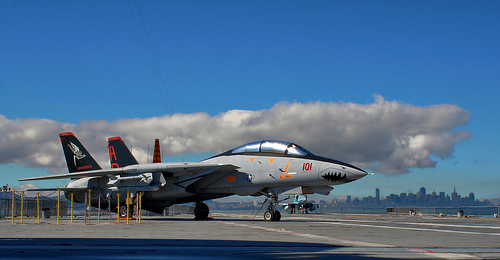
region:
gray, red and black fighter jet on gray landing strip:
[26, 126, 366, 215]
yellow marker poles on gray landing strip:
[0, 178, 156, 235]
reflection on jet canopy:
[216, 128, 314, 164]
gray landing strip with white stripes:
[341, 215, 479, 254]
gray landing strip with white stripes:
[168, 225, 360, 258]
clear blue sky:
[16, 15, 203, 100]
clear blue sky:
[168, 16, 345, 83]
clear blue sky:
[291, 10, 494, 92]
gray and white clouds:
[258, 95, 468, 138]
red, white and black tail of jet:
[46, 119, 105, 167]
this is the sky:
[112, 20, 290, 112]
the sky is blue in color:
[118, 15, 308, 92]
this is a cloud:
[265, 105, 420, 140]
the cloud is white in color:
[288, 105, 458, 139]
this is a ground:
[331, 220, 451, 251]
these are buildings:
[372, 182, 479, 205]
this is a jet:
[62, 134, 351, 219]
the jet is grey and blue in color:
[98, 134, 366, 236]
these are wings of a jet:
[32, 155, 242, 182]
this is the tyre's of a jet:
[187, 202, 217, 222]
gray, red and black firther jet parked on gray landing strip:
[35, 121, 385, 233]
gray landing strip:
[50, 223, 265, 254]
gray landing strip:
[293, 217, 483, 254]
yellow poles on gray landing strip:
[6, 180, 151, 241]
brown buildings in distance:
[353, 189, 498, 221]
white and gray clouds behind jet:
[3, 111, 180, 161]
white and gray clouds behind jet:
[151, 115, 367, 167]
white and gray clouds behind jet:
[272, 79, 472, 171]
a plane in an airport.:
[13, 122, 375, 237]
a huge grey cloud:
[0, 97, 478, 179]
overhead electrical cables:
[125, 5, 202, 156]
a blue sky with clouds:
[3, 2, 497, 192]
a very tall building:
[372, 183, 381, 200]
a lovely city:
[153, 184, 498, 211]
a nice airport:
[1, 131, 498, 257]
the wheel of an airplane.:
[263, 206, 282, 223]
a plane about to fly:
[16, 120, 371, 231]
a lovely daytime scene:
[0, 0, 498, 257]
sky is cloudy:
[416, 71, 477, 196]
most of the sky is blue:
[311, 38, 450, 85]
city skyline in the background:
[412, 178, 458, 213]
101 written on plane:
[295, 160, 330, 185]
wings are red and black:
[53, 108, 172, 205]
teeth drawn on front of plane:
[315, 158, 391, 216]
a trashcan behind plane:
[38, 198, 65, 238]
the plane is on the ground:
[69, 100, 337, 254]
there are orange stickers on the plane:
[236, 146, 353, 236]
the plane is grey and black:
[194, 142, 239, 177]